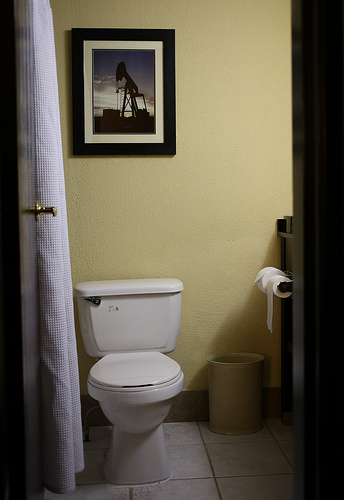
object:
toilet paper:
[75, 279, 185, 485]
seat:
[88, 350, 184, 395]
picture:
[72, 27, 176, 154]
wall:
[213, 54, 254, 117]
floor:
[196, 448, 256, 478]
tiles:
[234, 434, 272, 489]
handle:
[85, 294, 102, 307]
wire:
[83, 402, 103, 441]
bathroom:
[0, 0, 344, 498]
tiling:
[193, 446, 216, 493]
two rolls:
[252, 265, 292, 334]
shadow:
[215, 313, 270, 345]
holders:
[279, 280, 291, 293]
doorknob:
[34, 200, 56, 222]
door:
[5, 30, 57, 499]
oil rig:
[112, 56, 150, 130]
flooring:
[179, 433, 200, 451]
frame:
[78, 27, 169, 44]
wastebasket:
[206, 351, 267, 431]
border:
[122, 38, 165, 51]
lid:
[90, 348, 179, 388]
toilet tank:
[74, 275, 184, 356]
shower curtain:
[33, 21, 62, 168]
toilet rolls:
[252, 265, 282, 294]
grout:
[206, 454, 216, 479]